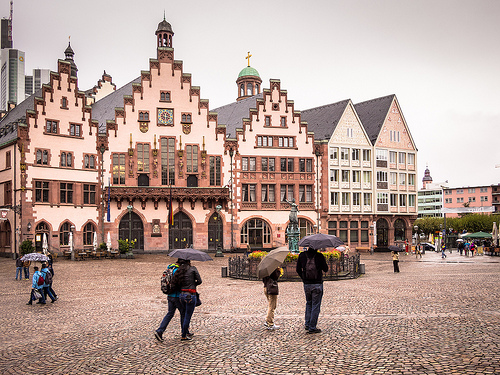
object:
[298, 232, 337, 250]
umbrella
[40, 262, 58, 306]
person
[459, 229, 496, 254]
tent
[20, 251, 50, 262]
umbrella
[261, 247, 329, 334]
couple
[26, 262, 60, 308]
couple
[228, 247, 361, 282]
fence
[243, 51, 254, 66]
cross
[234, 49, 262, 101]
tower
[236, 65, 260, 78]
dome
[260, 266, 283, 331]
woman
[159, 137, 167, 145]
window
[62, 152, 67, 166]
window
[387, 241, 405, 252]
umbrella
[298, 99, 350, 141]
roof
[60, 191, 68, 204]
windows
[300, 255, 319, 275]
backpack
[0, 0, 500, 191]
sky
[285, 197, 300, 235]
statue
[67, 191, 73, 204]
windows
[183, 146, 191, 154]
windows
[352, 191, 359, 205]
windows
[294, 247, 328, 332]
people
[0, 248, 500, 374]
street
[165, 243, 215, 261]
umbrella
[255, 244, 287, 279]
umbrella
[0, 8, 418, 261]
building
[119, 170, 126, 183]
window